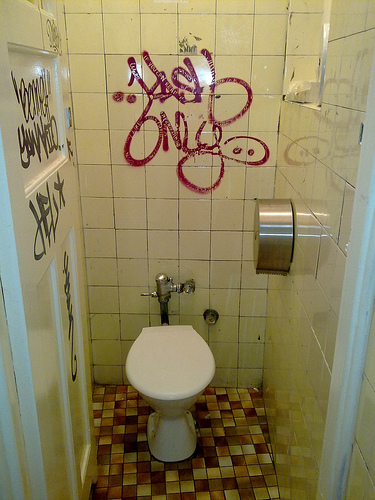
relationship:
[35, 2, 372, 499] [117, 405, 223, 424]
bathroom has tank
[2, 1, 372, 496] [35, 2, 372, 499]
photo of bathroom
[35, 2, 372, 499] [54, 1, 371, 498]
bathroom has stall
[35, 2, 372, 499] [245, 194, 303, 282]
bathroom has toilet paper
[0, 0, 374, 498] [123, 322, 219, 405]
bathroom has lid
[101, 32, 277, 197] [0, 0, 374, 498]
graffiti behind bathroom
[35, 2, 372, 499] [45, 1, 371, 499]
wall has tiles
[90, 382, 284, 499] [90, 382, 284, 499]
floor has floor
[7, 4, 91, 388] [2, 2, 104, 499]
graffiti on top of door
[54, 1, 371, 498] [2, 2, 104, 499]
stall has door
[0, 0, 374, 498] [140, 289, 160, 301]
bathroom has handle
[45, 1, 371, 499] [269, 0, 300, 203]
tiles have grout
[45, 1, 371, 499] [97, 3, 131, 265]
tiles have grout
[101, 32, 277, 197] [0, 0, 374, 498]
graffiti above bathroom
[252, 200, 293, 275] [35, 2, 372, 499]
toilet paper hangs on wall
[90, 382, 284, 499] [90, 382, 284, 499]
floor on floor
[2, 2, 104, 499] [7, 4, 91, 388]
door has graffiti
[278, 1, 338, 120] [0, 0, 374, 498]
window above bathroom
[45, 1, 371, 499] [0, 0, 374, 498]
tiles surround bathroom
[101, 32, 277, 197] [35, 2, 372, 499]
graffiti on wall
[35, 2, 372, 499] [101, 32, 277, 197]
wall has graffiti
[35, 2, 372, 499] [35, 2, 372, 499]
bathroom has wall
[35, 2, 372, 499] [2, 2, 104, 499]
bathroom has door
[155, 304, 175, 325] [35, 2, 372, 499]
pipe on wall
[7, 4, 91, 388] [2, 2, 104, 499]
graffiti on door